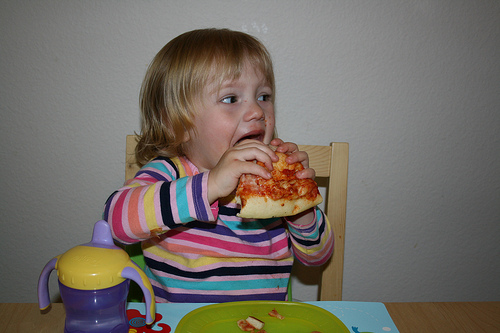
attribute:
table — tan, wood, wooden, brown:
[4, 301, 500, 331]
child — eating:
[101, 26, 368, 314]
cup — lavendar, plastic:
[18, 215, 180, 332]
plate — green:
[167, 297, 366, 332]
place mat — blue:
[115, 290, 404, 332]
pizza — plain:
[232, 133, 329, 223]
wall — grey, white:
[341, 16, 499, 301]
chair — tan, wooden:
[97, 118, 364, 304]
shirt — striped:
[98, 155, 337, 296]